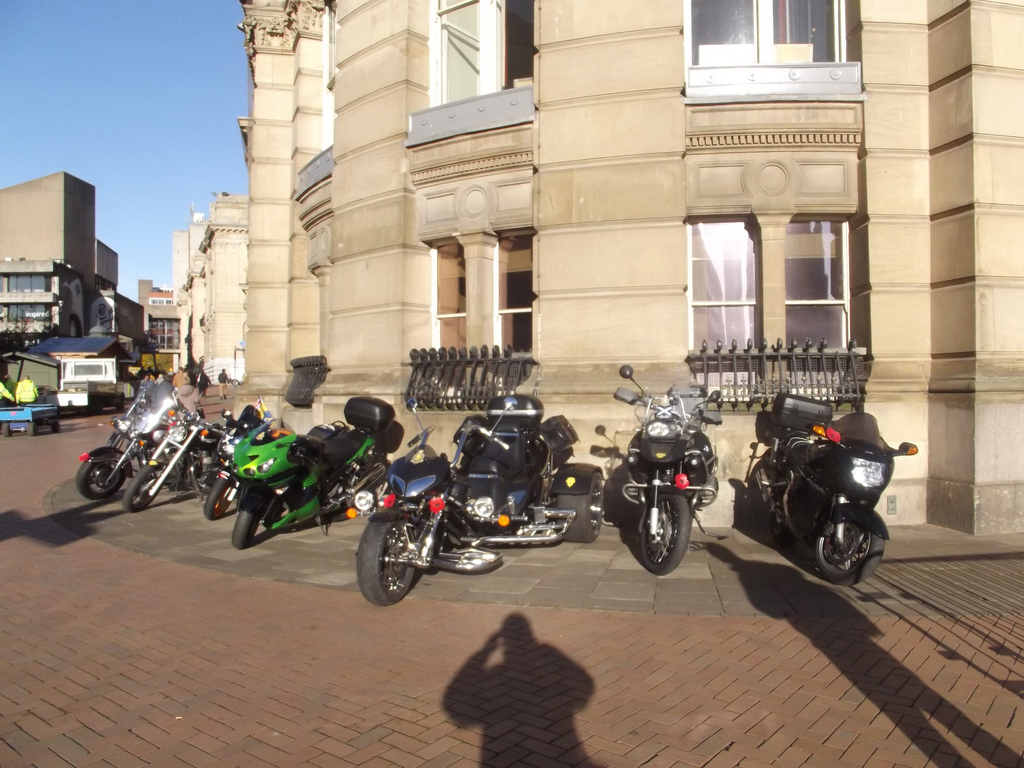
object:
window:
[685, 216, 765, 403]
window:
[785, 211, 850, 394]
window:
[429, 239, 467, 349]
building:
[172, 0, 1024, 562]